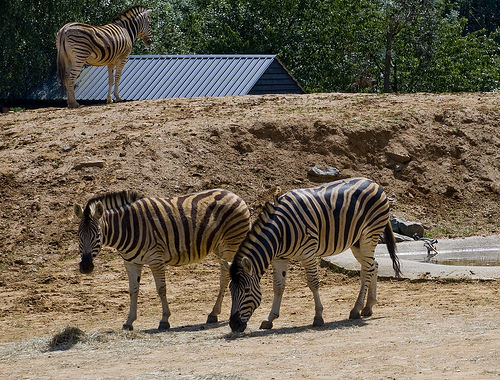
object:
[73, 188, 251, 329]
zebra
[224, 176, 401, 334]
zebra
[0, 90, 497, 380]
ground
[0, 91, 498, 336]
mud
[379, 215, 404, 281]
tail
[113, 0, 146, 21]
mane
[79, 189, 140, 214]
mane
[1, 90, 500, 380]
dirt mountain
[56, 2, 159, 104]
zebra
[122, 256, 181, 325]
legs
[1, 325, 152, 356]
grass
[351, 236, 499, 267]
watering hole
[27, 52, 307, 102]
roof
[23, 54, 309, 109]
building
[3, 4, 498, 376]
scene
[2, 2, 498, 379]
zoo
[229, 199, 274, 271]
mane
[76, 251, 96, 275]
muzzle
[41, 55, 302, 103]
wood building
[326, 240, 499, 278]
cement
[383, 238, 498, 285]
basin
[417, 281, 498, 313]
foundation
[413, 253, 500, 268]
hole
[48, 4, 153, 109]
zebra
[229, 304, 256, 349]
muzzle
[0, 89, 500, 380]
dirt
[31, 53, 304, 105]
roof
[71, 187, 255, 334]
zebra